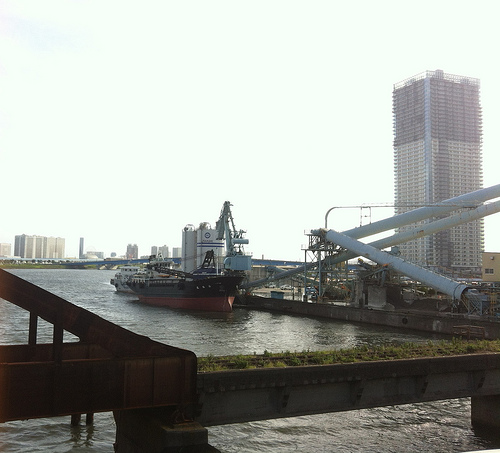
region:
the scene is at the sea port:
[7, 132, 491, 382]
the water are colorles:
[187, 310, 299, 350]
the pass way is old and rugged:
[228, 327, 497, 399]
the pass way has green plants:
[263, 333, 468, 383]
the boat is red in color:
[146, 284, 240, 306]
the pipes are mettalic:
[346, 221, 435, 311]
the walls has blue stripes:
[188, 235, 227, 250]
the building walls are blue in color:
[183, 223, 197, 261]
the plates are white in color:
[226, 230, 263, 277]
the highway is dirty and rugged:
[197, 373, 471, 408]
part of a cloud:
[288, 60, 338, 107]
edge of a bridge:
[290, 363, 326, 404]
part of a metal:
[143, 364, 199, 436]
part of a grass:
[378, 335, 405, 357]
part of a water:
[322, 425, 338, 438]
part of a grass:
[326, 343, 351, 368]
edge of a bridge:
[330, 384, 367, 420]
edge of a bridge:
[326, 351, 343, 369]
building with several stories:
[385, 56, 488, 282]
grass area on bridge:
[199, 348, 430, 361]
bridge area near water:
[3, 250, 496, 445]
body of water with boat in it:
[14, 267, 472, 443]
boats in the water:
[107, 256, 239, 314]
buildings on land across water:
[1, 229, 174, 258]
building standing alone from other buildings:
[74, 235, 86, 255]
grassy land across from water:
[7, 261, 63, 269]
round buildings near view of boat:
[181, 218, 222, 265]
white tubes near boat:
[329, 181, 496, 301]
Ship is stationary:
[100, 253, 263, 323]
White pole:
[305, 192, 499, 310]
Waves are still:
[34, 269, 84, 286]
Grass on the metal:
[199, 333, 493, 375]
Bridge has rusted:
[7, 256, 496, 451]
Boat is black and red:
[123, 256, 284, 327]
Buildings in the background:
[13, 227, 118, 264]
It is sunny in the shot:
[65, 49, 286, 184]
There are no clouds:
[133, 50, 328, 154]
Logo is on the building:
[197, 230, 224, 252]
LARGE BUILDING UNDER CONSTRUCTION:
[366, 45, 494, 218]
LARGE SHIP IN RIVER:
[120, 230, 298, 337]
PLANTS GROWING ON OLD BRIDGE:
[202, 309, 497, 380]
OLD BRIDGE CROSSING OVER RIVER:
[191, 311, 432, 426]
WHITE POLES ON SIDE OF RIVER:
[297, 190, 493, 316]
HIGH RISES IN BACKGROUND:
[15, 230, 140, 275]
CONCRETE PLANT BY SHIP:
[177, 198, 241, 273]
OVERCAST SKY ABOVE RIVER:
[199, 116, 381, 291]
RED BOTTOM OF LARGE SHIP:
[131, 284, 254, 334]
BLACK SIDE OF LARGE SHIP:
[111, 254, 244, 318]